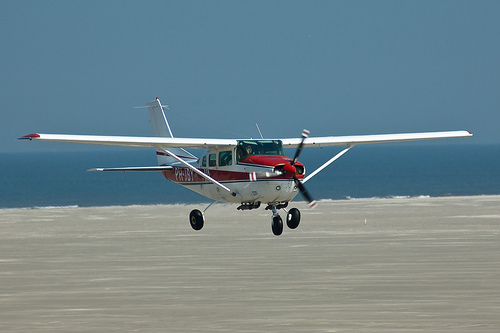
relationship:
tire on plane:
[271, 214, 283, 236] [17, 96, 473, 236]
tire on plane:
[284, 205, 302, 229] [17, 96, 473, 236]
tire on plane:
[188, 206, 204, 230] [17, 96, 473, 236]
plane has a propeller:
[17, 96, 473, 236] [250, 128, 319, 207]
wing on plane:
[15, 128, 475, 151] [17, 96, 473, 236]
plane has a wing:
[17, 96, 473, 236] [83, 164, 172, 174]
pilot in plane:
[240, 144, 255, 157] [17, 96, 473, 236]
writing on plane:
[172, 166, 198, 181] [17, 96, 473, 236]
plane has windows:
[17, 96, 473, 236] [196, 151, 231, 168]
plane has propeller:
[17, 96, 473, 236] [250, 128, 319, 207]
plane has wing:
[17, 96, 473, 236] [15, 128, 475, 151]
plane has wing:
[17, 96, 473, 236] [83, 164, 172, 174]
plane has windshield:
[17, 96, 473, 236] [233, 142, 280, 159]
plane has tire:
[17, 96, 473, 236] [271, 214, 283, 236]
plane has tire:
[17, 96, 473, 236] [284, 205, 302, 229]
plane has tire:
[17, 96, 473, 236] [188, 206, 204, 230]